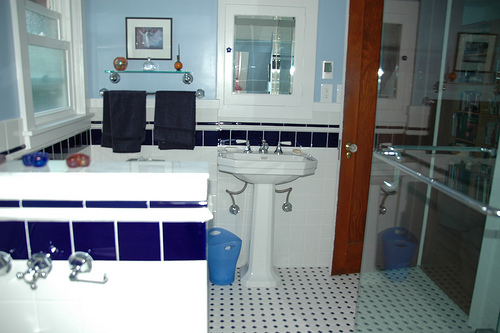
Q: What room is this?
A: It is a bathroom.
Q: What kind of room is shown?
A: It is a bathroom.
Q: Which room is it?
A: It is a bathroom.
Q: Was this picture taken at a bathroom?
A: Yes, it was taken in a bathroom.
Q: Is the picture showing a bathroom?
A: Yes, it is showing a bathroom.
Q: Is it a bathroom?
A: Yes, it is a bathroom.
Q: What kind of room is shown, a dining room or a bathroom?
A: It is a bathroom.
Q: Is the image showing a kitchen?
A: No, the picture is showing a bathroom.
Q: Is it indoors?
A: Yes, it is indoors.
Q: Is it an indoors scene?
A: Yes, it is indoors.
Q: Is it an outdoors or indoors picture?
A: It is indoors.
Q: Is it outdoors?
A: No, it is indoors.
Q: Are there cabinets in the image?
A: Yes, there is a cabinet.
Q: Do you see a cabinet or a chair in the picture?
A: Yes, there is a cabinet.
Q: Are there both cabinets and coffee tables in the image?
A: No, there is a cabinet but no coffee tables.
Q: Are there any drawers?
A: No, there are no drawers.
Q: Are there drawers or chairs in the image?
A: No, there are no drawers or chairs.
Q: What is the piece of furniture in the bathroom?
A: The piece of furniture is a cabinet.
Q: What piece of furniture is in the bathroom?
A: The piece of furniture is a cabinet.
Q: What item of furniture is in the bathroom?
A: The piece of furniture is a cabinet.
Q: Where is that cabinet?
A: The cabinet is in the bathroom.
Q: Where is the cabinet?
A: The cabinet is in the bathroom.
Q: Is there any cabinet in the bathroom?
A: Yes, there is a cabinet in the bathroom.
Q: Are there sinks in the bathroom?
A: No, there is a cabinet in the bathroom.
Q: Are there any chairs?
A: No, there are no chairs.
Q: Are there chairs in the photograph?
A: No, there are no chairs.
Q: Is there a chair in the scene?
A: No, there are no chairs.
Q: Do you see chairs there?
A: No, there are no chairs.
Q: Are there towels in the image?
A: Yes, there is a towel.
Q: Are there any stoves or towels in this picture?
A: Yes, there is a towel.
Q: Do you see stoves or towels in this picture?
A: Yes, there is a towel.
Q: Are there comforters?
A: No, there are no comforters.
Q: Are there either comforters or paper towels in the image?
A: No, there are no comforters or paper towels.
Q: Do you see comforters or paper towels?
A: No, there are no comforters or paper towels.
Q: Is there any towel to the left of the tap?
A: Yes, there is a towel to the left of the tap.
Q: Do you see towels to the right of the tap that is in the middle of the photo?
A: No, the towel is to the left of the faucet.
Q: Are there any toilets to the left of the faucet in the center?
A: No, there is a towel to the left of the tap.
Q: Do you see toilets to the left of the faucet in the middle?
A: No, there is a towel to the left of the tap.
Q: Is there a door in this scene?
A: Yes, there is a door.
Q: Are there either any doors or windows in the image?
A: Yes, there is a door.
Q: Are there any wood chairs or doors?
A: Yes, there is a wood door.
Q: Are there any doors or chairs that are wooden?
A: Yes, the door is wooden.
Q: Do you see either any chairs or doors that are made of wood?
A: Yes, the door is made of wood.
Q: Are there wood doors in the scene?
A: Yes, there is a wood door.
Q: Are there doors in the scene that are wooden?
A: Yes, there is a door that is wooden.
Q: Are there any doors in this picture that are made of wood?
A: Yes, there is a door that is made of wood.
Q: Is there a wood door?
A: Yes, there is a door that is made of wood.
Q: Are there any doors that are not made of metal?
A: Yes, there is a door that is made of wood.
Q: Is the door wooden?
A: Yes, the door is wooden.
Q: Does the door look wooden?
A: Yes, the door is wooden.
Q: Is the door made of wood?
A: Yes, the door is made of wood.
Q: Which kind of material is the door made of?
A: The door is made of wood.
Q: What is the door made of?
A: The door is made of wood.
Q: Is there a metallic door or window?
A: No, there is a door but it is wooden.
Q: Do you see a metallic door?
A: No, there is a door but it is wooden.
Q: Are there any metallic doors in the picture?
A: No, there is a door but it is wooden.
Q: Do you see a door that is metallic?
A: No, there is a door but it is wooden.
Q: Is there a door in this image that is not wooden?
A: No, there is a door but it is wooden.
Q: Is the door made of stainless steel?
A: No, the door is made of wood.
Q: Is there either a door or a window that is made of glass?
A: No, there is a door but it is made of wood.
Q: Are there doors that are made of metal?
A: No, there is a door but it is made of wood.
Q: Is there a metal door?
A: No, there is a door but it is made of wood.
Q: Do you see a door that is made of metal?
A: No, there is a door but it is made of wood.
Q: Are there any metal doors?
A: No, there is a door but it is made of wood.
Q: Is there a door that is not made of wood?
A: No, there is a door but it is made of wood.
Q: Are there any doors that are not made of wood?
A: No, there is a door but it is made of wood.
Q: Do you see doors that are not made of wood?
A: No, there is a door but it is made of wood.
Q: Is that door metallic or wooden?
A: The door is wooden.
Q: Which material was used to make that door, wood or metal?
A: The door is made of wood.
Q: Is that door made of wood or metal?
A: The door is made of wood.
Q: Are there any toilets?
A: No, there are no toilets.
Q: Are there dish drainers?
A: No, there are no dish drainers.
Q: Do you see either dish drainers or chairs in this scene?
A: No, there are no dish drainers or chairs.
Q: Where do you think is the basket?
A: The basket is in the bathroom.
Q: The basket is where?
A: The basket is in the bathroom.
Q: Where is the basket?
A: The basket is in the bathroom.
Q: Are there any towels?
A: Yes, there is a towel.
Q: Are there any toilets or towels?
A: Yes, there is a towel.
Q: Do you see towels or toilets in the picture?
A: Yes, there is a towel.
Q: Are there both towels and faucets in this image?
A: Yes, there are both a towel and a faucet.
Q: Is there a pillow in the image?
A: No, there are no pillows.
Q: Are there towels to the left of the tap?
A: Yes, there is a towel to the left of the tap.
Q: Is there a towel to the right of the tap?
A: No, the towel is to the left of the tap.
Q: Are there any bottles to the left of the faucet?
A: No, there is a towel to the left of the faucet.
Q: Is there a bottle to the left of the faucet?
A: No, there is a towel to the left of the faucet.